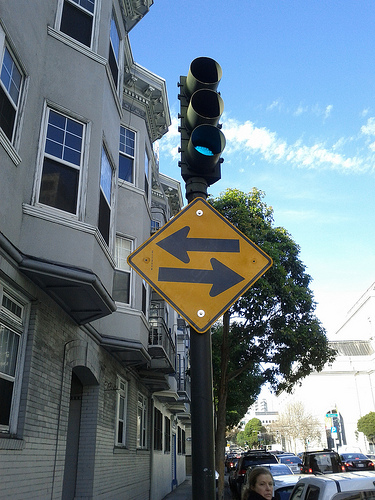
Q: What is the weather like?
A: It is clear.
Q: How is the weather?
A: It is clear.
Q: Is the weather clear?
A: Yes, it is clear.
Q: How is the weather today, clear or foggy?
A: It is clear.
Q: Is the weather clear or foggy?
A: It is clear.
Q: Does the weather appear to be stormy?
A: No, it is clear.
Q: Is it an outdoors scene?
A: Yes, it is outdoors.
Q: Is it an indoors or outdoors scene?
A: It is outdoors.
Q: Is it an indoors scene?
A: No, it is outdoors.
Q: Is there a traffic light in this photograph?
A: Yes, there is a traffic light.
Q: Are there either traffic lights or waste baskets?
A: Yes, there is a traffic light.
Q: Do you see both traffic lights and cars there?
A: Yes, there are both a traffic light and a car.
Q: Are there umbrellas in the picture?
A: No, there are no umbrellas.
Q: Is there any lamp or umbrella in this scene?
A: No, there are no umbrellas or lamps.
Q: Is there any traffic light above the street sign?
A: Yes, there is a traffic light above the street sign.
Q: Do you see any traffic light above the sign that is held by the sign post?
A: Yes, there is a traffic light above the street sign.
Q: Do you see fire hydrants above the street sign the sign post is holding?
A: No, there is a traffic light above the street sign.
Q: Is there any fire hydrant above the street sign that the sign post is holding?
A: No, there is a traffic light above the street sign.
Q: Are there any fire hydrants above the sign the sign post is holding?
A: No, there is a traffic light above the street sign.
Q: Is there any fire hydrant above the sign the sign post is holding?
A: No, there is a traffic light above the street sign.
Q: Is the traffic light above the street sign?
A: Yes, the traffic light is above the street sign.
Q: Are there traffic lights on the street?
A: Yes, there is a traffic light on the street.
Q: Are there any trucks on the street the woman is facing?
A: No, there is a traffic light on the street.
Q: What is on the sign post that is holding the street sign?
A: The traffic light is on the sign post.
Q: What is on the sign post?
A: The traffic light is on the sign post.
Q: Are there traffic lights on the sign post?
A: Yes, there is a traffic light on the sign post.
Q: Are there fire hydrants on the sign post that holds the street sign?
A: No, there is a traffic light on the sign post.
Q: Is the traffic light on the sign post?
A: Yes, the traffic light is on the sign post.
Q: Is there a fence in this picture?
A: No, there are no fences.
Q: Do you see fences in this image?
A: No, there are no fences.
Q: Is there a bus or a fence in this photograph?
A: No, there are no fences or buses.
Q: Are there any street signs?
A: Yes, there is a street sign.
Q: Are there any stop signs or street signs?
A: Yes, there is a street sign.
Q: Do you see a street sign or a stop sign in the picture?
A: Yes, there is a street sign.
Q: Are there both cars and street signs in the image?
A: Yes, there are both a street sign and a car.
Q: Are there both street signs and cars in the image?
A: Yes, there are both a street sign and a car.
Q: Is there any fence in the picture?
A: No, there are no fences.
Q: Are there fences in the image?
A: No, there are no fences.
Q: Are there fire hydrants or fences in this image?
A: No, there are no fences or fire hydrants.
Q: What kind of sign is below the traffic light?
A: The sign is a street sign.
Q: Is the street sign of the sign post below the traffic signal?
A: Yes, the street sign is below the traffic signal.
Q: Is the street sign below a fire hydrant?
A: No, the street sign is below the traffic signal.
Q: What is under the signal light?
A: The street sign is under the signal light.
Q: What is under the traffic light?
A: The street sign is under the signal light.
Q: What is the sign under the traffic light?
A: The sign is a street sign.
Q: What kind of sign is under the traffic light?
A: The sign is a street sign.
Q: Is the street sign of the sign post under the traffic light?
A: Yes, the street sign is under the traffic light.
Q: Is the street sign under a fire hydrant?
A: No, the street sign is under the traffic light.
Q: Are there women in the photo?
A: Yes, there is a woman.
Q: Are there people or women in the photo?
A: Yes, there is a woman.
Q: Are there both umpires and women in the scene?
A: No, there is a woman but no umpires.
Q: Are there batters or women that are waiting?
A: Yes, the woman is waiting.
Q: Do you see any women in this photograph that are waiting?
A: Yes, there is a woman that is waiting.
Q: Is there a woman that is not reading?
A: Yes, there is a woman that is waiting.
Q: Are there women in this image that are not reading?
A: Yes, there is a woman that is waiting.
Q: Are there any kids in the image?
A: No, there are no kids.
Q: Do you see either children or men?
A: No, there are no children or men.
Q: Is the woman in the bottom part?
A: Yes, the woman is in the bottom of the image.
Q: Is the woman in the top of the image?
A: No, the woman is in the bottom of the image.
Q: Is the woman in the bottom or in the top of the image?
A: The woman is in the bottom of the image.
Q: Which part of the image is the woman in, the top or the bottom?
A: The woman is in the bottom of the image.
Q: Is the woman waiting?
A: Yes, the woman is waiting.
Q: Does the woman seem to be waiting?
A: Yes, the woman is waiting.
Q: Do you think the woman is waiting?
A: Yes, the woman is waiting.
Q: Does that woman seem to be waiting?
A: Yes, the woman is waiting.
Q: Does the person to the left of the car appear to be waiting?
A: Yes, the woman is waiting.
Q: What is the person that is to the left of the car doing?
A: The woman is waiting.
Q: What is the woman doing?
A: The woman is waiting.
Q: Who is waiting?
A: The woman is waiting.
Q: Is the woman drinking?
A: No, the woman is waiting.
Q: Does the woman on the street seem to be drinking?
A: No, the woman is waiting.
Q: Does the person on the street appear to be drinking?
A: No, the woman is waiting.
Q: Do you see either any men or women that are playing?
A: No, there is a woman but she is waiting.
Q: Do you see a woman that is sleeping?
A: No, there is a woman but she is waiting.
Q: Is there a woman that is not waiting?
A: No, there is a woman but she is waiting.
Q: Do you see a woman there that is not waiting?
A: No, there is a woman but she is waiting.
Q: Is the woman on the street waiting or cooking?
A: The woman is waiting.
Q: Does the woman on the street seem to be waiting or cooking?
A: The woman is waiting.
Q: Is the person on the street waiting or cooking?
A: The woman is waiting.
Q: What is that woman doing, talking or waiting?
A: The woman is waiting.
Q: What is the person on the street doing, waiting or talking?
A: The woman is waiting.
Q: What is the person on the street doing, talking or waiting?
A: The woman is waiting.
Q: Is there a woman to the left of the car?
A: Yes, there is a woman to the left of the car.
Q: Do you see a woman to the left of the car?
A: Yes, there is a woman to the left of the car.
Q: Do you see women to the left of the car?
A: Yes, there is a woman to the left of the car.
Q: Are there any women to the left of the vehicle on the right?
A: Yes, there is a woman to the left of the car.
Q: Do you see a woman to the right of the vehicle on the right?
A: No, the woman is to the left of the car.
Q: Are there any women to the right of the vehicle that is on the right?
A: No, the woman is to the left of the car.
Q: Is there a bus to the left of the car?
A: No, there is a woman to the left of the car.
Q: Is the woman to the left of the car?
A: Yes, the woman is to the left of the car.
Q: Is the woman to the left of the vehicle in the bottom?
A: Yes, the woman is to the left of the car.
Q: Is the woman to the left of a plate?
A: No, the woman is to the left of the car.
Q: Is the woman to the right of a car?
A: No, the woman is to the left of a car.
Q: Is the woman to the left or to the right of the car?
A: The woman is to the left of the car.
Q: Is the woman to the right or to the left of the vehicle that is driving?
A: The woman is to the left of the car.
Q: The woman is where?
A: The woman is on the street.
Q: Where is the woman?
A: The woman is on the street.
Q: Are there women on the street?
A: Yes, there is a woman on the street.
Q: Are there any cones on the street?
A: No, there is a woman on the street.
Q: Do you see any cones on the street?
A: No, there is a woman on the street.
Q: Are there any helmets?
A: No, there are no helmets.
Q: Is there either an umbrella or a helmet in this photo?
A: No, there are no helmets or umbrellas.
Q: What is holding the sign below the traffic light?
A: The sign post is holding the street sign.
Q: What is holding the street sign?
A: The sign post is holding the street sign.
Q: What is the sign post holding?
A: The sign post is holding the street sign.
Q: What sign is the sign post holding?
A: The sign post is holding the street sign.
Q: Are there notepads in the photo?
A: No, there are no notepads.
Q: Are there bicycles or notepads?
A: No, there are no notepads or bicycles.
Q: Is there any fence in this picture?
A: No, there are no fences.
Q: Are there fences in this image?
A: No, there are no fences.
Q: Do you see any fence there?
A: No, there are no fences.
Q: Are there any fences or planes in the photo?
A: No, there are no fences or planes.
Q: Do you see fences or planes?
A: No, there are no fences or planes.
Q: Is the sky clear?
A: Yes, the sky is clear.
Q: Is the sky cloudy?
A: No, the sky is clear.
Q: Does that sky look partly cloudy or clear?
A: The sky is clear.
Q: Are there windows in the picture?
A: Yes, there are windows.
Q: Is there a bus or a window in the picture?
A: Yes, there are windows.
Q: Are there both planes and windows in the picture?
A: No, there are windows but no airplanes.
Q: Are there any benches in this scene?
A: No, there are no benches.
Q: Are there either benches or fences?
A: No, there are no benches or fences.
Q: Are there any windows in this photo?
A: Yes, there is a window.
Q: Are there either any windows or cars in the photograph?
A: Yes, there is a window.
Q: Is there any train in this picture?
A: No, there are no trains.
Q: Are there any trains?
A: No, there are no trains.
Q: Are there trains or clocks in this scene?
A: No, there are no trains or clocks.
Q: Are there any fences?
A: No, there are no fences.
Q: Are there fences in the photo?
A: No, there are no fences.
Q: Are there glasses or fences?
A: No, there are no fences or glasses.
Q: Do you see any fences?
A: No, there are no fences.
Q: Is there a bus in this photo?
A: No, there are no buses.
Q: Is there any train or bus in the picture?
A: No, there are no buses or trains.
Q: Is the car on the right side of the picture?
A: Yes, the car is on the right of the image.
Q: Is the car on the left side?
A: No, the car is on the right of the image.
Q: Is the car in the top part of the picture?
A: No, the car is in the bottom of the image.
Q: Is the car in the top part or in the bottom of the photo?
A: The car is in the bottom of the image.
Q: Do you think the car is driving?
A: Yes, the car is driving.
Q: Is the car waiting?
A: No, the car is driving.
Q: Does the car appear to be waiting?
A: No, the car is driving.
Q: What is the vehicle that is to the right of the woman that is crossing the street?
A: The vehicle is a car.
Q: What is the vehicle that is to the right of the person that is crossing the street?
A: The vehicle is a car.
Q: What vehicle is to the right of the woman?
A: The vehicle is a car.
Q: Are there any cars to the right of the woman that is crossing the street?
A: Yes, there is a car to the right of the woman.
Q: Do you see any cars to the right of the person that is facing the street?
A: Yes, there is a car to the right of the woman.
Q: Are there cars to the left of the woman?
A: No, the car is to the right of the woman.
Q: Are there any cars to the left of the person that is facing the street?
A: No, the car is to the right of the woman.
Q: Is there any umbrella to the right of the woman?
A: No, there is a car to the right of the woman.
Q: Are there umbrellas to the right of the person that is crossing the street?
A: No, there is a car to the right of the woman.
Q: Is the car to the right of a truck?
A: No, the car is to the right of the woman.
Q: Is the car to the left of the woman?
A: No, the car is to the right of the woman.